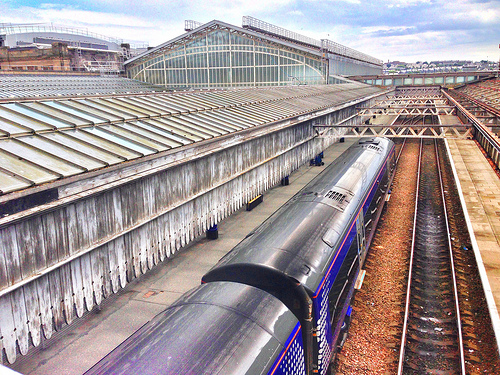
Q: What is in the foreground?
A: A train.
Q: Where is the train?
A: In the train station.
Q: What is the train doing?
A: Waiting at the station.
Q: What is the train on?
A: Train tracks.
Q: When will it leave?
A: When it is loaded.